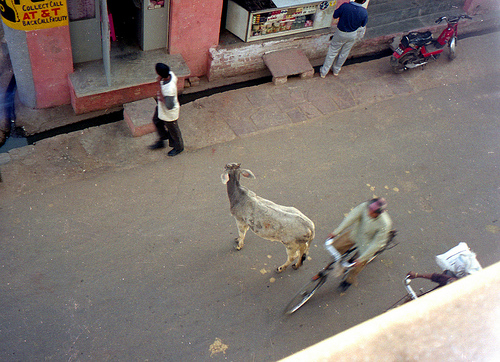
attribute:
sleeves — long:
[322, 209, 357, 235]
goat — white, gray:
[177, 140, 362, 285]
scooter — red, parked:
[384, 11, 471, 76]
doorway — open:
[95, 1, 159, 61]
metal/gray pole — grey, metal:
[96, 0, 116, 88]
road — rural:
[61, 164, 453, 349]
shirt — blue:
[331, 2, 368, 30]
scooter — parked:
[391, 14, 463, 71]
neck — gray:
[225, 178, 245, 208]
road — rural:
[0, 22, 497, 360]